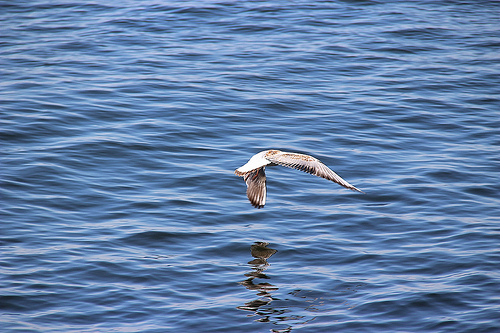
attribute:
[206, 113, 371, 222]
bird — flying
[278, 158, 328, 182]
wing tips — black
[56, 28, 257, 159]
water — deep, blue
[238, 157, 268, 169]
tail — white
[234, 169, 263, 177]
feathers — brown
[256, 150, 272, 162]
back — white, feathered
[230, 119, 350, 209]
bird — flying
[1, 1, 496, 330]
waves — small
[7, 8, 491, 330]
water — calm, glassy, sea, deep dark blue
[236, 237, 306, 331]
reflection — seagull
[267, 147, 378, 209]
wing — extended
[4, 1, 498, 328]
image — beautiful, of sea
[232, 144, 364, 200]
seagull — flying